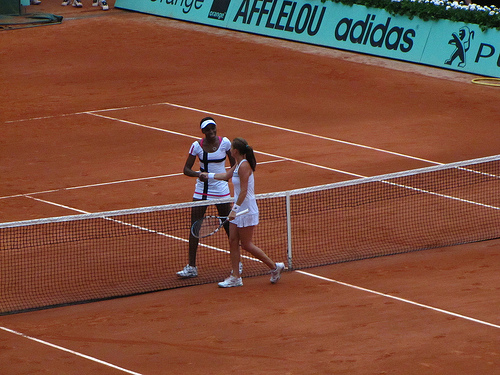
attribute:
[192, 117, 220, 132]
headband — white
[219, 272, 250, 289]
shoe — tennis, woman's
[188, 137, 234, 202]
tennis dress — standard, white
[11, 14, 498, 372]
court — clay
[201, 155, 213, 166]
stripe — vertical, pink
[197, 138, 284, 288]
player — female, tennis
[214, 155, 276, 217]
tank top — white, woman's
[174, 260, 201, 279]
tennis sneaker — white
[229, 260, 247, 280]
tennis sneaker — white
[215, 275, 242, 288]
tennis sneaker — white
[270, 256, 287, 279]
tennis sneaker — white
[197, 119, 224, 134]
visor — white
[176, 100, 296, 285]
athletes — hand-shaking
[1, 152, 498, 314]
net — tennis, black, white, regulation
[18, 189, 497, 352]
line — white, long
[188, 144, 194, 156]
stripe — pink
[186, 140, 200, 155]
sleeve — short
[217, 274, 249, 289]
sneaker — white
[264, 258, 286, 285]
sneaker — white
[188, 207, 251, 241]
racket — large, tennis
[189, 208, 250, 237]
racket — blue, tennis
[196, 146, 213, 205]
stripe — black, vertical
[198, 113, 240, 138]
visor — white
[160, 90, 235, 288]
player — black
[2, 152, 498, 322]
tennis net — long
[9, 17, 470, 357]
court — tennis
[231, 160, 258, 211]
shirt — sleeveless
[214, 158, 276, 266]
dress — white, tennis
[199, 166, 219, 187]
wristband — white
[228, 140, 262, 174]
hair — long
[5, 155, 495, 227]
top — white